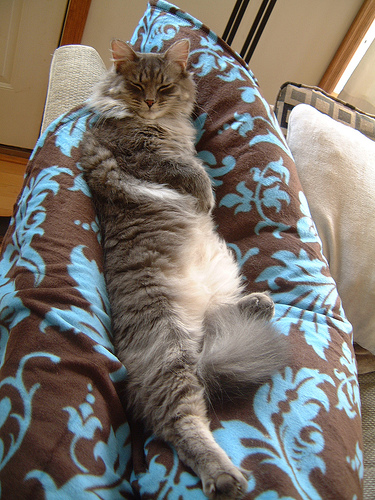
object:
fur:
[112, 212, 190, 315]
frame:
[317, 0, 375, 101]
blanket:
[0, 0, 363, 500]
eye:
[155, 80, 173, 95]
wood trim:
[54, 0, 90, 48]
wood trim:
[0, 145, 32, 164]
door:
[0, 1, 68, 151]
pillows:
[271, 80, 373, 139]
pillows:
[287, 103, 375, 354]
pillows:
[1, 1, 364, 500]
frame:
[54, 1, 91, 58]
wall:
[80, 0, 373, 107]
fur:
[173, 220, 238, 327]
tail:
[200, 303, 290, 391]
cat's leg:
[204, 294, 247, 335]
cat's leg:
[169, 409, 229, 474]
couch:
[3, 43, 375, 497]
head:
[97, 30, 202, 121]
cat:
[76, 29, 293, 499]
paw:
[199, 466, 250, 498]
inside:
[1, 1, 374, 498]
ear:
[162, 37, 191, 68]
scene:
[23, 31, 314, 320]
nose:
[145, 94, 155, 111]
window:
[334, 23, 373, 113]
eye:
[130, 77, 144, 93]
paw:
[235, 290, 275, 325]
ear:
[109, 36, 135, 70]